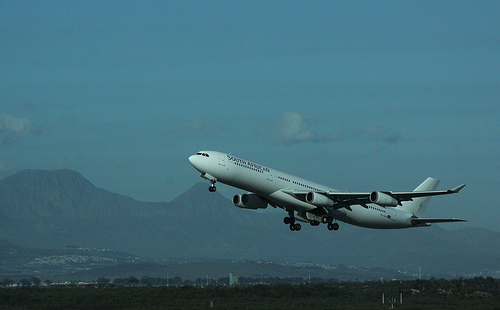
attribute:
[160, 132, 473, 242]
plane — white, flying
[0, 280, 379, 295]
trees — green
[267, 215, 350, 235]
wheels — down, black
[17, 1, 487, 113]
sky — blue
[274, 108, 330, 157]
cloud — white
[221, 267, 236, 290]
building — tall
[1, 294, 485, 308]
ground — brown